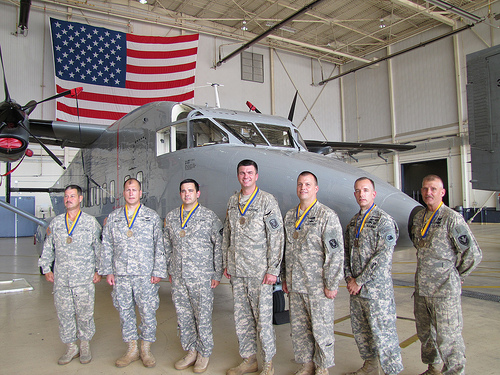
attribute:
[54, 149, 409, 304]
soldiers — standing, here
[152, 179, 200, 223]
medal — gold, here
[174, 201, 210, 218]
neck — here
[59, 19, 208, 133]
flag — blue, hanging, red, american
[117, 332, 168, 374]
boots — khaki, tan, combat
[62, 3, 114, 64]
stars — white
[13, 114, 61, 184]
propeller — red, black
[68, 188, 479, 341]
men — military, infront, posing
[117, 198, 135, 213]
ribbon — yellow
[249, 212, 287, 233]
patch — green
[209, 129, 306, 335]
man — tall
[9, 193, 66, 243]
doors — blue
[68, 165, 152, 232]
windows — rowed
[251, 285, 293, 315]
wheels — held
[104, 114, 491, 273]
airplane — parked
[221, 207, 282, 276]
uniform — army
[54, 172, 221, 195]
haircuts — military